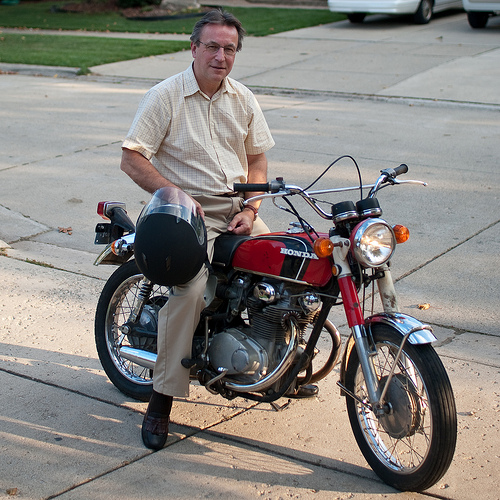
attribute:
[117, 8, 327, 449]
man — sitting, smirking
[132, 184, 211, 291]
helmet — black, motorcycle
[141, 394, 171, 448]
shoe — dress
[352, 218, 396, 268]
headlight — off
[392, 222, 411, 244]
turn signal — orange, bright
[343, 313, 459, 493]
wheel — black, round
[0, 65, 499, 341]
street — grey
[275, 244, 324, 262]
logo — white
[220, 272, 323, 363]
engine — silver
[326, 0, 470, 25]
car — parked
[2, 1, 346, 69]
grass — pictured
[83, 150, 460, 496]
motorcycle — red, black